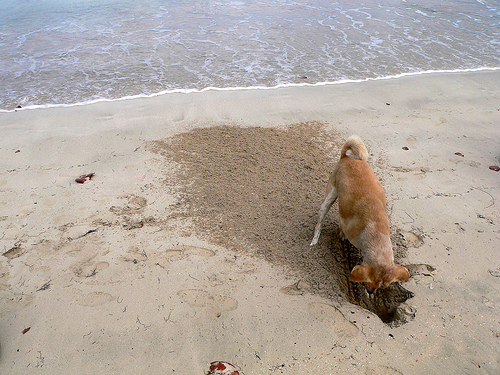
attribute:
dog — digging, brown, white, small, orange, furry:
[316, 138, 415, 290]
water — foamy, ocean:
[1, 3, 499, 107]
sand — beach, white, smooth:
[12, 74, 497, 373]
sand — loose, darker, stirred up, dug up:
[207, 128, 315, 231]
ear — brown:
[349, 260, 370, 289]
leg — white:
[306, 184, 339, 250]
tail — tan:
[340, 134, 370, 162]